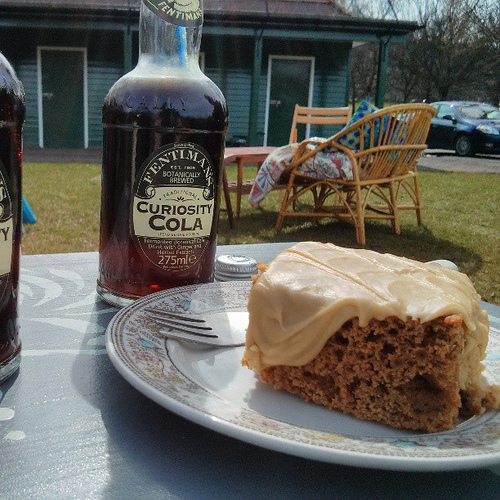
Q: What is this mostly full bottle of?
A: Curiosity Cola.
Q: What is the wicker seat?
A: Loveseat bench.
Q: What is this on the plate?
A: A piece of light brown, messily frosted cake.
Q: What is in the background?
A: Greenish blue building with a long front porch.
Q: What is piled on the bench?
A: Pillows and blankets.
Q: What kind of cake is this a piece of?
A: Carrot cake.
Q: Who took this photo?
A: Jackson Mingus.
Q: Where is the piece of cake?
A: On a plate.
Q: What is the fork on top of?
A: A plate.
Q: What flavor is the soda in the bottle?
A: Cola.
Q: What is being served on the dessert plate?
A: A piece of cake.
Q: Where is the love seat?
A: In the yard.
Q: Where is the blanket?
A: On the loveseat.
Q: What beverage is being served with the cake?
A: A bottle of soda.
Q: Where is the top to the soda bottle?
A: Next to the bottle.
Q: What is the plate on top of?
A: A table.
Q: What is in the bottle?
A: Cola.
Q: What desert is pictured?
A: Cake.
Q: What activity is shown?
A: A picnic.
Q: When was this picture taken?
A: Daytime.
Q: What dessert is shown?
A: Cake.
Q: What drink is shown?
A: Cola.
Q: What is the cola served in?
A: A bottle.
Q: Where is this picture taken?
A: A back yard.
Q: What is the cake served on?
A: A plate.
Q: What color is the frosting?
A: Caramel.